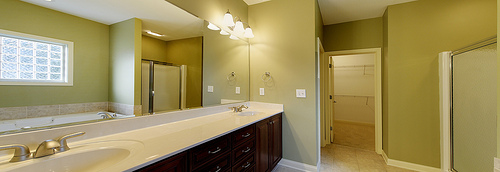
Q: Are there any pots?
A: No, there are no pots.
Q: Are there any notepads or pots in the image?
A: No, there are no pots or notepads.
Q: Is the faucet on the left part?
A: Yes, the faucet is on the left of the image.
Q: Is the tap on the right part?
A: No, the tap is on the left of the image.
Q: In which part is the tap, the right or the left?
A: The tap is on the left of the image.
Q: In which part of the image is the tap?
A: The tap is on the left of the image.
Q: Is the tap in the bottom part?
A: Yes, the tap is in the bottom of the image.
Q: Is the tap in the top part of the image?
A: No, the tap is in the bottom of the image.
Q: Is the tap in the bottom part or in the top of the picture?
A: The tap is in the bottom of the image.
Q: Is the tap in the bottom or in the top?
A: The tap is in the bottom of the image.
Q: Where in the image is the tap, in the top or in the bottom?
A: The tap is in the bottom of the image.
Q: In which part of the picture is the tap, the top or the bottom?
A: The tap is in the bottom of the image.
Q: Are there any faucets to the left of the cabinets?
A: Yes, there is a faucet to the left of the cabinets.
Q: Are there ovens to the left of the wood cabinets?
A: No, there is a faucet to the left of the cabinets.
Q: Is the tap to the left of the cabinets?
A: Yes, the tap is to the left of the cabinets.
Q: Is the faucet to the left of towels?
A: No, the faucet is to the left of the cabinets.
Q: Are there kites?
A: No, there are no kites.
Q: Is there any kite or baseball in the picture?
A: No, there are no kites or baseballs.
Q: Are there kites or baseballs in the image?
A: No, there are no kites or baseballs.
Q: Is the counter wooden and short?
A: No, the counter is wooden but long.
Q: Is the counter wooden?
A: Yes, the counter is wooden.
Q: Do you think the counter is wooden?
A: Yes, the counter is wooden.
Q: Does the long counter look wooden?
A: Yes, the counter is wooden.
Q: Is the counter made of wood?
A: Yes, the counter is made of wood.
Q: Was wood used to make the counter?
A: Yes, the counter is made of wood.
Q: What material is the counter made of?
A: The counter is made of wood.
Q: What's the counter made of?
A: The counter is made of wood.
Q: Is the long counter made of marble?
A: No, the counter is made of wood.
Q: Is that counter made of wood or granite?
A: The counter is made of wood.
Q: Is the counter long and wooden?
A: Yes, the counter is long and wooden.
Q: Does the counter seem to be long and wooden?
A: Yes, the counter is long and wooden.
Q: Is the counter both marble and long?
A: No, the counter is long but wooden.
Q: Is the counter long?
A: Yes, the counter is long.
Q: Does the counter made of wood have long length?
A: Yes, the counter is long.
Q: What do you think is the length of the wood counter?
A: The counter is long.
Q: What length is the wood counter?
A: The counter is long.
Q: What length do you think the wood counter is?
A: The counter is long.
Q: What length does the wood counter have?
A: The counter has long length.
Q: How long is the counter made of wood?
A: The counter is long.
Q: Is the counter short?
A: No, the counter is long.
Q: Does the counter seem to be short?
A: No, the counter is long.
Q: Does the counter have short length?
A: No, the counter is long.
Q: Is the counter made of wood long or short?
A: The counter is long.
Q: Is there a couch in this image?
A: No, there are no couches.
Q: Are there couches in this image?
A: No, there are no couches.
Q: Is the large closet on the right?
A: Yes, the closet is on the right of the image.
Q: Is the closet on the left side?
A: No, the closet is on the right of the image.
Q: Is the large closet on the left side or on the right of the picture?
A: The closet is on the right of the image.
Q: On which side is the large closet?
A: The closet is on the right of the image.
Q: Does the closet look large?
A: Yes, the closet is large.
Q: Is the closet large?
A: Yes, the closet is large.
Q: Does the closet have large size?
A: Yes, the closet is large.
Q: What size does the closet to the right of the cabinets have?
A: The closet has large size.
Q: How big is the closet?
A: The closet is large.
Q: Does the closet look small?
A: No, the closet is large.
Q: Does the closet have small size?
A: No, the closet is large.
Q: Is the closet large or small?
A: The closet is large.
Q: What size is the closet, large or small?
A: The closet is large.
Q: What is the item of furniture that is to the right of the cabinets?
A: The piece of furniture is a closet.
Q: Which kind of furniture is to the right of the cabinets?
A: The piece of furniture is a closet.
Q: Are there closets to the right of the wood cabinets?
A: Yes, there is a closet to the right of the cabinets.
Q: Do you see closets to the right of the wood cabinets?
A: Yes, there is a closet to the right of the cabinets.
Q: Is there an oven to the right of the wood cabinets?
A: No, there is a closet to the right of the cabinets.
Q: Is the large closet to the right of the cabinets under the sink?
A: Yes, the closet is to the right of the cabinets.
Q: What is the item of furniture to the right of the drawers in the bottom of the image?
A: The piece of furniture is a closet.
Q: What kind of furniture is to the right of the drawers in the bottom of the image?
A: The piece of furniture is a closet.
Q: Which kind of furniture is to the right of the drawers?
A: The piece of furniture is a closet.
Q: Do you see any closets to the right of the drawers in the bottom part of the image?
A: Yes, there is a closet to the right of the drawers.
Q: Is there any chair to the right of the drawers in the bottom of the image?
A: No, there is a closet to the right of the drawers.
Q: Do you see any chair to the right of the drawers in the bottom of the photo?
A: No, there is a closet to the right of the drawers.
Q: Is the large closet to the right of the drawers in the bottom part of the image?
A: Yes, the closet is to the right of the drawers.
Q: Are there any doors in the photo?
A: Yes, there is a door.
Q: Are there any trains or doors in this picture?
A: Yes, there is a door.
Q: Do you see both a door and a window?
A: Yes, there are both a door and a window.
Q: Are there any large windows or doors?
A: Yes, there is a large door.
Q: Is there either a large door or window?
A: Yes, there is a large door.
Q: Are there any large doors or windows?
A: Yes, there is a large door.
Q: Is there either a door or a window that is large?
A: Yes, the door is large.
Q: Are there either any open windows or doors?
A: Yes, there is an open door.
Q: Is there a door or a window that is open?
A: Yes, the door is open.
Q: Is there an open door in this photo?
A: Yes, there is an open door.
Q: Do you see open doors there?
A: Yes, there is an open door.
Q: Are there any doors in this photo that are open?
A: Yes, there is a door that is open.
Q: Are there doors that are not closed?
A: Yes, there is a open door.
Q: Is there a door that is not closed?
A: Yes, there is a open door.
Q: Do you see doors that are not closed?
A: Yes, there is a open door.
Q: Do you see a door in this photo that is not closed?
A: Yes, there is a open door.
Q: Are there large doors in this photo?
A: Yes, there is a large door.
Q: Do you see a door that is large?
A: Yes, there is a door that is large.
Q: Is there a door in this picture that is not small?
A: Yes, there is a large door.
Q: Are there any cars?
A: No, there are no cars.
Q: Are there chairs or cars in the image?
A: No, there are no cars or chairs.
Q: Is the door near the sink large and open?
A: Yes, the door is large and open.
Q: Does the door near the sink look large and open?
A: Yes, the door is large and open.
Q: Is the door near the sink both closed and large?
A: No, the door is large but open.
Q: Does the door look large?
A: Yes, the door is large.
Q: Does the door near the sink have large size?
A: Yes, the door is large.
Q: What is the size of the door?
A: The door is large.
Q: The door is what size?
A: The door is large.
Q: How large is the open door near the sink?
A: The door is large.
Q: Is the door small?
A: No, the door is large.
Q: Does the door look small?
A: No, the door is large.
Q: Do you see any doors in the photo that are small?
A: No, there is a door but it is large.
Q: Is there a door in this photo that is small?
A: No, there is a door but it is large.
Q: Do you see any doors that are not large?
A: No, there is a door but it is large.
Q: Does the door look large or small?
A: The door is large.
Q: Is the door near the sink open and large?
A: Yes, the door is open and large.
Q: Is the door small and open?
A: No, the door is open but large.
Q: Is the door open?
A: Yes, the door is open.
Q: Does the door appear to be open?
A: Yes, the door is open.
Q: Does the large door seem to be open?
A: Yes, the door is open.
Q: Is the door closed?
A: No, the door is open.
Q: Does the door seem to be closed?
A: No, the door is open.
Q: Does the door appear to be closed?
A: No, the door is open.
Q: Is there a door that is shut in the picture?
A: No, there is a door but it is open.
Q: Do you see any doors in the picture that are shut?
A: No, there is a door but it is open.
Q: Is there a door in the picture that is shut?
A: No, there is a door but it is open.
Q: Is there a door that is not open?
A: No, there is a door but it is open.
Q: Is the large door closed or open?
A: The door is open.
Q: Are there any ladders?
A: No, there are no ladders.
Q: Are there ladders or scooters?
A: No, there are no ladders or scooters.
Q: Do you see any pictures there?
A: No, there are no pictures.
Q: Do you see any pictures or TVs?
A: No, there are no pictures or tvs.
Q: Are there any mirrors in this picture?
A: Yes, there is a mirror.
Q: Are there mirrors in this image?
A: Yes, there is a mirror.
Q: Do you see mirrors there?
A: Yes, there is a mirror.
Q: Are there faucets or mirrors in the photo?
A: Yes, there is a mirror.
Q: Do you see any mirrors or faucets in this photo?
A: Yes, there is a mirror.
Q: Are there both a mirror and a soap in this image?
A: No, there is a mirror but no soaps.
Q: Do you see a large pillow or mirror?
A: Yes, there is a large mirror.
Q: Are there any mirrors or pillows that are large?
A: Yes, the mirror is large.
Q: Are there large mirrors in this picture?
A: Yes, there is a large mirror.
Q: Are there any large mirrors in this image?
A: Yes, there is a large mirror.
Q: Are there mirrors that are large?
A: Yes, there is a mirror that is large.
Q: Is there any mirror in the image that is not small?
A: Yes, there is a large mirror.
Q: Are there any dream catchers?
A: No, there are no dream catchers.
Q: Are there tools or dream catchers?
A: No, there are no dream catchers or tools.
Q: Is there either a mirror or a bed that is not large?
A: No, there is a mirror but it is large.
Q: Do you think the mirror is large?
A: Yes, the mirror is large.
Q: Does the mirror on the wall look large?
A: Yes, the mirror is large.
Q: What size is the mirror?
A: The mirror is large.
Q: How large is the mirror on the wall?
A: The mirror is large.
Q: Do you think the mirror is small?
A: No, the mirror is large.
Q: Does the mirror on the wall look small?
A: No, the mirror is large.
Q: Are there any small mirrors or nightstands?
A: No, there is a mirror but it is large.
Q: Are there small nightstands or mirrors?
A: No, there is a mirror but it is large.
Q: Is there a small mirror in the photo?
A: No, there is a mirror but it is large.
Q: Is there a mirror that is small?
A: No, there is a mirror but it is large.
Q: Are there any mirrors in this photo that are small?
A: No, there is a mirror but it is large.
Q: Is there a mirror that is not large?
A: No, there is a mirror but it is large.